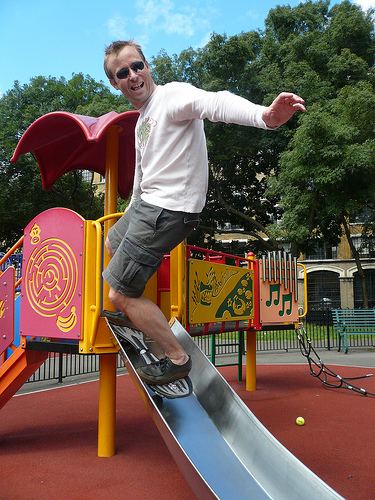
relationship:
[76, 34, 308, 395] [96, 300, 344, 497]
man skating on slide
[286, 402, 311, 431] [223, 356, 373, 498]
tennis ball on ground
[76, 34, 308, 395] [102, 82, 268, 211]
man has sweater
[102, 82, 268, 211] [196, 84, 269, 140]
sweater has sleeve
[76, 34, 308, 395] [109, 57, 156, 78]
man has sunglasses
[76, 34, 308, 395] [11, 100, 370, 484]
man in playground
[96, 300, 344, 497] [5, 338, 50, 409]
slide has stairs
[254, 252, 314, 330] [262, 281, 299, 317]
board has musical notes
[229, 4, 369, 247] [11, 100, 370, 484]
trees near playground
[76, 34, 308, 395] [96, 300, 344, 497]
man going down slide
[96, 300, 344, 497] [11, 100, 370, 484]
slide in playground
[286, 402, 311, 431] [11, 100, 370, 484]
tennis ball in playground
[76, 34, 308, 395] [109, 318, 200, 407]
man has skateboard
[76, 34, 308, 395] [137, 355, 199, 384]
man has shoe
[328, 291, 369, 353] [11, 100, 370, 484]
bench near playground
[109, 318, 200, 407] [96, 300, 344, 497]
skateboard on slide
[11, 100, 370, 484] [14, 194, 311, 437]
playground has jungle gym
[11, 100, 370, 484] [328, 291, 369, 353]
playground has bench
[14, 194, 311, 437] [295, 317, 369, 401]
jungle gym has ladder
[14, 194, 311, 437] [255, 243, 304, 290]
jungle gym has instruments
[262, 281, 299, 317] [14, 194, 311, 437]
musical notes on jungle gym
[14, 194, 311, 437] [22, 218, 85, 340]
jungle gym has maze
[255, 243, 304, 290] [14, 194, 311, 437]
instruments on jungle gym